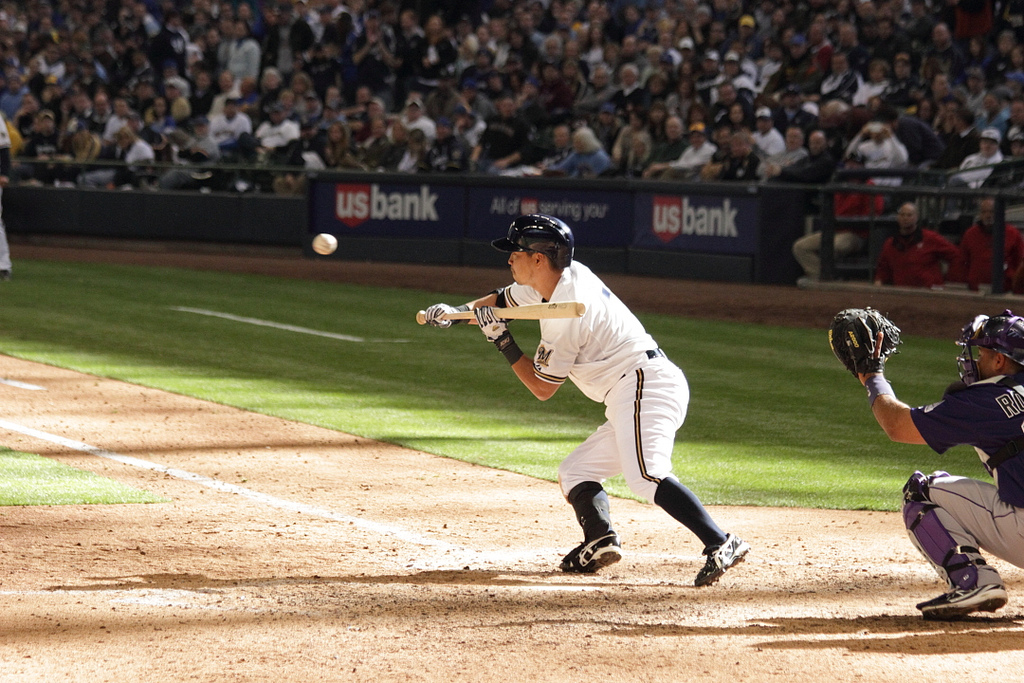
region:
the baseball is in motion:
[311, 231, 338, 257]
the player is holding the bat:
[412, 211, 749, 585]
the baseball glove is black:
[827, 300, 903, 374]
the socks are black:
[566, 474, 728, 551]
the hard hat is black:
[492, 212, 572, 276]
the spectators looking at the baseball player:
[0, 4, 1021, 616]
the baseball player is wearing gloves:
[416, 208, 749, 585]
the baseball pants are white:
[557, 351, 691, 500]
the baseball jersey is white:
[506, 256, 659, 403]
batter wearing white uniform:
[425, 211, 749, 589]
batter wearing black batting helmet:
[430, 211, 754, 588]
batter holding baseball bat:
[415, 214, 751, 591]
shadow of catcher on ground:
[456, 611, 1022, 656]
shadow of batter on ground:
[43, 568, 695, 589]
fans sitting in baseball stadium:
[0, 0, 1022, 194]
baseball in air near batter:
[311, 231, 338, 257]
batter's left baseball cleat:
[694, 531, 749, 588]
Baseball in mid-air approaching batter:
[301, 217, 347, 265]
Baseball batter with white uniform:
[402, 187, 756, 595]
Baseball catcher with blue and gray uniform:
[808, 281, 1004, 630]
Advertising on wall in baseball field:
[326, 171, 447, 236]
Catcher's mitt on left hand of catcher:
[816, 291, 909, 386]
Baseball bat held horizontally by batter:
[402, 287, 593, 336]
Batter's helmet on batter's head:
[490, 202, 583, 275]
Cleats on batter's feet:
[551, 524, 754, 591]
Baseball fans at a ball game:
[10, 12, 1022, 209]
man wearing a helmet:
[403, 188, 745, 618]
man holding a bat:
[408, 198, 762, 625]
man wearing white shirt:
[416, 201, 742, 591]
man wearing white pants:
[380, 178, 779, 597]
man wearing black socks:
[419, 187, 751, 614]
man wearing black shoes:
[416, 198, 759, 629]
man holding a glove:
[811, 264, 1018, 601]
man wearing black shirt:
[832, 258, 1017, 625]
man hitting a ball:
[288, 222, 747, 597]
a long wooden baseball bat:
[413, 288, 587, 333]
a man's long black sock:
[650, 476, 731, 554]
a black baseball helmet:
[495, 208, 579, 259]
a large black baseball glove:
[820, 303, 910, 379]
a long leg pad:
[898, 470, 978, 585]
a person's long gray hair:
[574, 127, 603, 153]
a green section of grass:
[0, 246, 1003, 512]